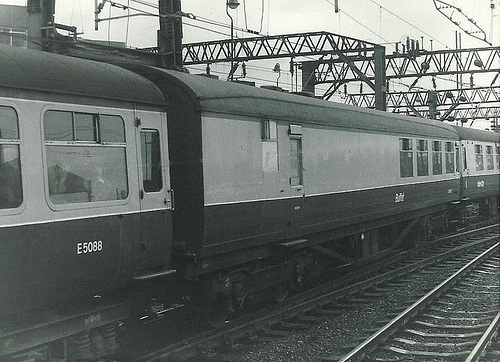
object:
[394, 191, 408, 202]
number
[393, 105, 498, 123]
metal beam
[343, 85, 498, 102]
metal beam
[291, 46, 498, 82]
metal beam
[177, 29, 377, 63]
metal beam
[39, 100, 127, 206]
window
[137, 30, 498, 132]
scaffolding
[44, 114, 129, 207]
window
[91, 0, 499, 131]
power lines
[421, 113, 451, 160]
ground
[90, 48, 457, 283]
train car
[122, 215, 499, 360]
railway tracks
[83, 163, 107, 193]
people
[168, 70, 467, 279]
train truck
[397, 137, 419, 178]
windows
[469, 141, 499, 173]
windows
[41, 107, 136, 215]
windows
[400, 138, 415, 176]
window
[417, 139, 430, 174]
window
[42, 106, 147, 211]
window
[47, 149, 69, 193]
girl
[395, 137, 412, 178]
window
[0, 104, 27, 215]
window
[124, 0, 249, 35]
wire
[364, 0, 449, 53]
wire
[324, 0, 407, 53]
wire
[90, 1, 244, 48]
wire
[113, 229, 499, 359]
gravel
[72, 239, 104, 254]
number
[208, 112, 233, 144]
wall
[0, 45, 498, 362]
train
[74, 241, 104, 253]
white number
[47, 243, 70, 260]
black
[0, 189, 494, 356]
wheels